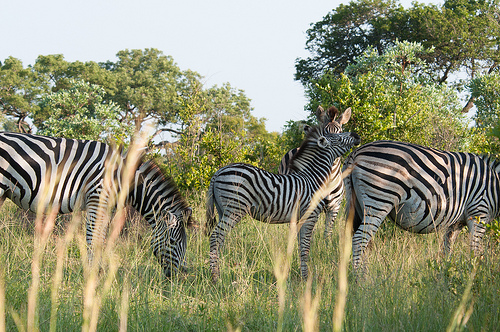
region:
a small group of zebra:
[1, 97, 491, 305]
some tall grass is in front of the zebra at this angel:
[21, 121, 484, 318]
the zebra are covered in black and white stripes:
[14, 110, 491, 290]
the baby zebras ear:
[313, 135, 333, 147]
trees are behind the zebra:
[15, 5, 498, 155]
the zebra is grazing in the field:
[123, 192, 193, 294]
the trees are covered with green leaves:
[326, 12, 477, 134]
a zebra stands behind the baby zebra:
[278, 134, 343, 237]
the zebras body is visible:
[393, 141, 466, 241]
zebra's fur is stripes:
[170, 96, 359, 302]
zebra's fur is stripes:
[196, 116, 353, 297]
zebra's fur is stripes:
[200, 104, 341, 294]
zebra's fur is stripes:
[187, 111, 366, 326]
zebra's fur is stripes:
[189, 97, 356, 328]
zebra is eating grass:
[95, 145, 216, 304]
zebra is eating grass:
[140, 186, 212, 316]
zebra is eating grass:
[140, 179, 200, 321]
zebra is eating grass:
[132, 177, 226, 328]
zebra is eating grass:
[117, 187, 202, 307]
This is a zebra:
[1, 122, 197, 299]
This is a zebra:
[189, 97, 363, 291]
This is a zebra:
[349, 121, 499, 290]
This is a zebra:
[0, 118, 200, 305]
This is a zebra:
[186, 95, 373, 297]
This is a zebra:
[339, 100, 492, 321]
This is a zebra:
[0, 110, 198, 320]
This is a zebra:
[183, 96, 366, 303]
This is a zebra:
[335, 68, 498, 309]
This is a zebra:
[1, 113, 197, 325]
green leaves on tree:
[51, 55, 64, 70]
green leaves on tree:
[136, 78, 141, 87]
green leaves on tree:
[170, 65, 177, 75]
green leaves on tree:
[259, 152, 270, 155]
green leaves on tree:
[334, 72, 339, 83]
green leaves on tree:
[406, 100, 414, 107]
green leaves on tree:
[440, 39, 451, 41]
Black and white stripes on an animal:
[143, 169, 195, 221]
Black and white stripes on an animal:
[118, 140, 156, 182]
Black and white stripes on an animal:
[78, 128, 121, 169]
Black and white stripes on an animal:
[40, 127, 86, 171]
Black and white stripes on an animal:
[18, 169, 60, 214]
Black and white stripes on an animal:
[200, 165, 240, 205]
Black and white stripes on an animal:
[238, 153, 278, 196]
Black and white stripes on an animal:
[278, 162, 312, 207]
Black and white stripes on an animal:
[388, 139, 432, 186]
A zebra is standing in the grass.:
[341, 143, 497, 287]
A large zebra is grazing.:
[1, 128, 191, 293]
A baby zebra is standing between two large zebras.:
[201, 105, 366, 285]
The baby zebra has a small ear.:
[317, 134, 331, 152]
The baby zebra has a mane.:
[280, 119, 333, 170]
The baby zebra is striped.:
[197, 102, 361, 287]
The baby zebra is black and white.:
[188, 105, 363, 289]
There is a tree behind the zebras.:
[104, 48, 258, 204]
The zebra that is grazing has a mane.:
[128, 140, 199, 230]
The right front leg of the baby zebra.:
[295, 212, 325, 290]